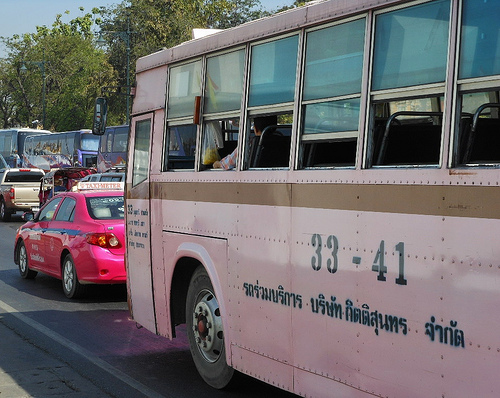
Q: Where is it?
A: This is at the street.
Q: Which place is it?
A: It is a street.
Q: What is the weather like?
A: It is clear.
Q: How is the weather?
A: It is clear.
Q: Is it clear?
A: Yes, it is clear.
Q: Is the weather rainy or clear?
A: It is clear.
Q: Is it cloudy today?
A: No, it is clear.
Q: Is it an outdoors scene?
A: Yes, it is outdoors.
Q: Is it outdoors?
A: Yes, it is outdoors.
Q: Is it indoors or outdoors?
A: It is outdoors.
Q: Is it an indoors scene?
A: No, it is outdoors.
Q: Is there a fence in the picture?
A: No, there are no fences.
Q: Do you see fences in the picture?
A: No, there are no fences.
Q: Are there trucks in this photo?
A: Yes, there is a truck.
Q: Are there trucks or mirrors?
A: Yes, there is a truck.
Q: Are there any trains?
A: No, there are no trains.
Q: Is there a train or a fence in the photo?
A: No, there are no trains or fences.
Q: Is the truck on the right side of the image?
A: No, the truck is on the left of the image.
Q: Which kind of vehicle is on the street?
A: The vehicle is a truck.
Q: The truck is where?
A: The truck is on the street.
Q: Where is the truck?
A: The truck is on the street.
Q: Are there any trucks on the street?
A: Yes, there is a truck on the street.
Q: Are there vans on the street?
A: No, there is a truck on the street.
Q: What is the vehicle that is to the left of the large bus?
A: The vehicle is a truck.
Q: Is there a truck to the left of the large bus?
A: Yes, there is a truck to the left of the bus.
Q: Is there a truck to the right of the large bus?
A: No, the truck is to the left of the bus.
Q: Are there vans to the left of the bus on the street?
A: No, there is a truck to the left of the bus.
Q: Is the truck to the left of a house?
A: No, the truck is to the left of a bus.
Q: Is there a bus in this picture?
A: Yes, there are buses.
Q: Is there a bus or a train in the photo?
A: Yes, there are buses.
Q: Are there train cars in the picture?
A: No, there are no train cars.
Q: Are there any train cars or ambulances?
A: No, there are no train cars or ambulances.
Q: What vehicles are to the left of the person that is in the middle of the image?
A: The vehicles are buses.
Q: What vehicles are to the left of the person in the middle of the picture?
A: The vehicles are buses.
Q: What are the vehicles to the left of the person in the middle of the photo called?
A: The vehicles are buses.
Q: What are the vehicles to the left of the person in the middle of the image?
A: The vehicles are buses.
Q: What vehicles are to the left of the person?
A: The vehicles are buses.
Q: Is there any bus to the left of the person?
A: Yes, there are buses to the left of the person.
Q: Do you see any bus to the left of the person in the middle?
A: Yes, there are buses to the left of the person.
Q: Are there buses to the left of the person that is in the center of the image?
A: Yes, there are buses to the left of the person.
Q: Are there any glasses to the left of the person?
A: No, there are buses to the left of the person.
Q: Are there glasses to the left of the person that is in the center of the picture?
A: No, there are buses to the left of the person.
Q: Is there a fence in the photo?
A: No, there are no fences.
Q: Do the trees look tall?
A: Yes, the trees are tall.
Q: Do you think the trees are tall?
A: Yes, the trees are tall.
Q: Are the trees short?
A: No, the trees are tall.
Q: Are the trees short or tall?
A: The trees are tall.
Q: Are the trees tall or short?
A: The trees are tall.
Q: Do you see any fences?
A: No, there are no fences.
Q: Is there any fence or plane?
A: No, there are no fences or airplanes.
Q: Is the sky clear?
A: Yes, the sky is clear.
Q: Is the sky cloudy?
A: No, the sky is clear.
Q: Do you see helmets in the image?
A: No, there are no helmets.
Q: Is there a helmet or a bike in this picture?
A: No, there are no helmets or bikes.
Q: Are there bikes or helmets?
A: No, there are no helmets or bikes.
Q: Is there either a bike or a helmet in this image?
A: No, there are no helmets or bikes.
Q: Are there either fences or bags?
A: No, there are no fences or bags.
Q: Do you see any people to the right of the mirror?
A: Yes, there is a person to the right of the mirror.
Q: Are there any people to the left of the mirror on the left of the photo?
A: No, the person is to the right of the mirror.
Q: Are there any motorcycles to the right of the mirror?
A: No, there is a person to the right of the mirror.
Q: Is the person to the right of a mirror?
A: Yes, the person is to the right of a mirror.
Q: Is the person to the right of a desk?
A: No, the person is to the right of a mirror.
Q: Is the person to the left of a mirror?
A: No, the person is to the right of a mirror.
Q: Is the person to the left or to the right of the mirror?
A: The person is to the right of the mirror.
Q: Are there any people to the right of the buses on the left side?
A: Yes, there is a person to the right of the buses.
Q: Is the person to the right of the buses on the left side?
A: Yes, the person is to the right of the buses.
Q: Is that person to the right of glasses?
A: No, the person is to the right of the buses.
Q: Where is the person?
A: The person is in the bus.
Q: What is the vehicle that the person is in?
A: The vehicle is a bus.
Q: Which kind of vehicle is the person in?
A: The person is in the bus.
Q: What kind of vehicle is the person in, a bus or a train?
A: The person is in a bus.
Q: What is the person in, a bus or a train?
A: The person is in a bus.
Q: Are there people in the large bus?
A: Yes, there is a person in the bus.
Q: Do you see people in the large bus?
A: Yes, there is a person in the bus.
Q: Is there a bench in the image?
A: No, there are no benches.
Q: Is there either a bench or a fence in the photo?
A: No, there are no benches or fences.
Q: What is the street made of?
A: The street is made of concrete.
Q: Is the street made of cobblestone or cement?
A: The street is made of cement.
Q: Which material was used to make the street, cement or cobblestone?
A: The street is made of cement.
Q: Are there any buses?
A: Yes, there is a bus.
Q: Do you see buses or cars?
A: Yes, there is a bus.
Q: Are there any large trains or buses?
A: Yes, there is a large bus.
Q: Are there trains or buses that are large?
A: Yes, the bus is large.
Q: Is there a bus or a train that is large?
A: Yes, the bus is large.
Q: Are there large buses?
A: Yes, there is a large bus.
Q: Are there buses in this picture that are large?
A: Yes, there is a bus that is large.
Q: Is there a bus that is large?
A: Yes, there is a bus that is large.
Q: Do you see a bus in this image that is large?
A: Yes, there is a bus that is large.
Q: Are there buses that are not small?
A: Yes, there is a large bus.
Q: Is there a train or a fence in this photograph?
A: No, there are no trains or fences.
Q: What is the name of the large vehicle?
A: The vehicle is a bus.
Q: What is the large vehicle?
A: The vehicle is a bus.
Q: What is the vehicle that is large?
A: The vehicle is a bus.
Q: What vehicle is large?
A: The vehicle is a bus.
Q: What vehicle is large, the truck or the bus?
A: The bus is large.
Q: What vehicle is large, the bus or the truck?
A: The bus is large.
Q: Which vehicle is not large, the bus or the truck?
A: The truck is not large.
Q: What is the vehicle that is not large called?
A: The vehicle is a truck.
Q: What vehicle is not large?
A: The vehicle is a truck.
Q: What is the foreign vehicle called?
A: The vehicle is a bus.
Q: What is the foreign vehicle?
A: The vehicle is a bus.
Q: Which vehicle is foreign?
A: The vehicle is a bus.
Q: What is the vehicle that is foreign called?
A: The vehicle is a bus.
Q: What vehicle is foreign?
A: The vehicle is a bus.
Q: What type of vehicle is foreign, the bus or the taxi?
A: The bus is foreign.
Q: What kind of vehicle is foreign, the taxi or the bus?
A: The bus is foreign.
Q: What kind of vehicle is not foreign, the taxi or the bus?
A: The taxi is not foreign.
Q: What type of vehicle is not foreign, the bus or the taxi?
A: The taxi is not foreign.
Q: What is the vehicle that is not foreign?
A: The vehicle is a taxi.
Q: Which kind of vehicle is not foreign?
A: The vehicle is a taxi.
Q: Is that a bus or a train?
A: That is a bus.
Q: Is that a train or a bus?
A: That is a bus.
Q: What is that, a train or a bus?
A: That is a bus.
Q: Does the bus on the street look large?
A: Yes, the bus is large.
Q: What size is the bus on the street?
A: The bus is large.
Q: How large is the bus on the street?
A: The bus is large.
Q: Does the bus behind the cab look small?
A: No, the bus is large.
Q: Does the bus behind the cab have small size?
A: No, the bus is large.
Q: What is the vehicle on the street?
A: The vehicle is a bus.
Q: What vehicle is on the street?
A: The vehicle is a bus.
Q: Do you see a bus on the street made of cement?
A: Yes, there is a bus on the street.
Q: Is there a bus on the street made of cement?
A: Yes, there is a bus on the street.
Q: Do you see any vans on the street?
A: No, there is a bus on the street.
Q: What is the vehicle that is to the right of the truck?
A: The vehicle is a bus.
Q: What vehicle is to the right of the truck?
A: The vehicle is a bus.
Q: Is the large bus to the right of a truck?
A: Yes, the bus is to the right of a truck.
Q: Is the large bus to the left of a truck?
A: No, the bus is to the right of a truck.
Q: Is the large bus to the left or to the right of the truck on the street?
A: The bus is to the right of the truck.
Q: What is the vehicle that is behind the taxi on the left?
A: The vehicle is a bus.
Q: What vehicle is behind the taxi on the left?
A: The vehicle is a bus.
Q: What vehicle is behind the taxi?
A: The vehicle is a bus.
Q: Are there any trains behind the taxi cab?
A: No, there is a bus behind the taxi cab.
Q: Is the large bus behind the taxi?
A: Yes, the bus is behind the taxi.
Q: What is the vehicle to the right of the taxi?
A: The vehicle is a bus.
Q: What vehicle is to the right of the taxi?
A: The vehicle is a bus.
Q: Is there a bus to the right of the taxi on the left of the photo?
A: Yes, there is a bus to the right of the taxi.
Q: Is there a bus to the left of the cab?
A: No, the bus is to the right of the cab.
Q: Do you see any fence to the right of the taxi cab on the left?
A: No, there is a bus to the right of the taxi.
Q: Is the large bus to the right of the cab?
A: Yes, the bus is to the right of the cab.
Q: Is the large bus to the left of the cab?
A: No, the bus is to the right of the cab.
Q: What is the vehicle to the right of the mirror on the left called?
A: The vehicle is a bus.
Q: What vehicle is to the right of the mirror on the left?
A: The vehicle is a bus.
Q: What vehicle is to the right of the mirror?
A: The vehicle is a bus.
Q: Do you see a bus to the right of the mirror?
A: Yes, there is a bus to the right of the mirror.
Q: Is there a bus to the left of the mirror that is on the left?
A: No, the bus is to the right of the mirror.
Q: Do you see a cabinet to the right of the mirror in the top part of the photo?
A: No, there is a bus to the right of the mirror.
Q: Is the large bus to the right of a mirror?
A: Yes, the bus is to the right of a mirror.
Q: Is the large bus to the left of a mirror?
A: No, the bus is to the right of a mirror.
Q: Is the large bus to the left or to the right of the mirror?
A: The bus is to the right of the mirror.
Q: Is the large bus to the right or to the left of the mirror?
A: The bus is to the right of the mirror.